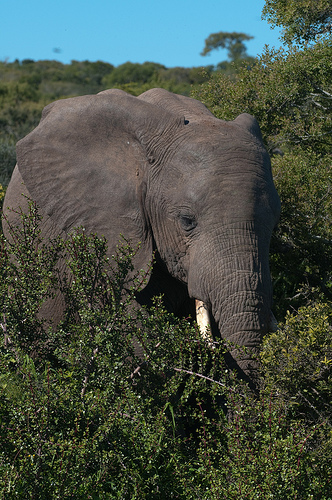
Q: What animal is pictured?
A: An elephant.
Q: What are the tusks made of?
A: Ivory.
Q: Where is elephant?
A: In the middle of green vegetation.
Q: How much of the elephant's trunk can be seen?
A: About half.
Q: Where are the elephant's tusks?
A: On either side of the elephant's trunk.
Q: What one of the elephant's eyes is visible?
A: The right eye.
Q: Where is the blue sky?
A: In the top of the image.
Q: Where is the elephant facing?
A: Toward the camera.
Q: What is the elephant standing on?
A: The ground.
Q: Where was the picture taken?
A: In the wild.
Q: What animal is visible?
A: Elephant.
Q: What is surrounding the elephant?
A: Trees.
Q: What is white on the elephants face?
A: Tusk.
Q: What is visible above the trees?
A: Sky.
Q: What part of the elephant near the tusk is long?
A: Trunk.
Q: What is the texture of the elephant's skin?
A: Wrinkled.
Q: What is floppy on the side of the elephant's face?
A: Ear.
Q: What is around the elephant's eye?
A: Wrinkles.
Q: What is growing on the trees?
A: Leaves.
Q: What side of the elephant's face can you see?
A: Right.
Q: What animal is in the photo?
A: Elephant.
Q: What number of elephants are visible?
A: One.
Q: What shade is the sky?
A: Blue.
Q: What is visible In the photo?
A: Elephant.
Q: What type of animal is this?
A: An elephant.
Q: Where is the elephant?
A: In the bushes.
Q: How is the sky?
A: Clear and blue.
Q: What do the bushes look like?
A: Green.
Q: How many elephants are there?
A: One.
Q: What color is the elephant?
A: Grey.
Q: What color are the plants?
A: Green.